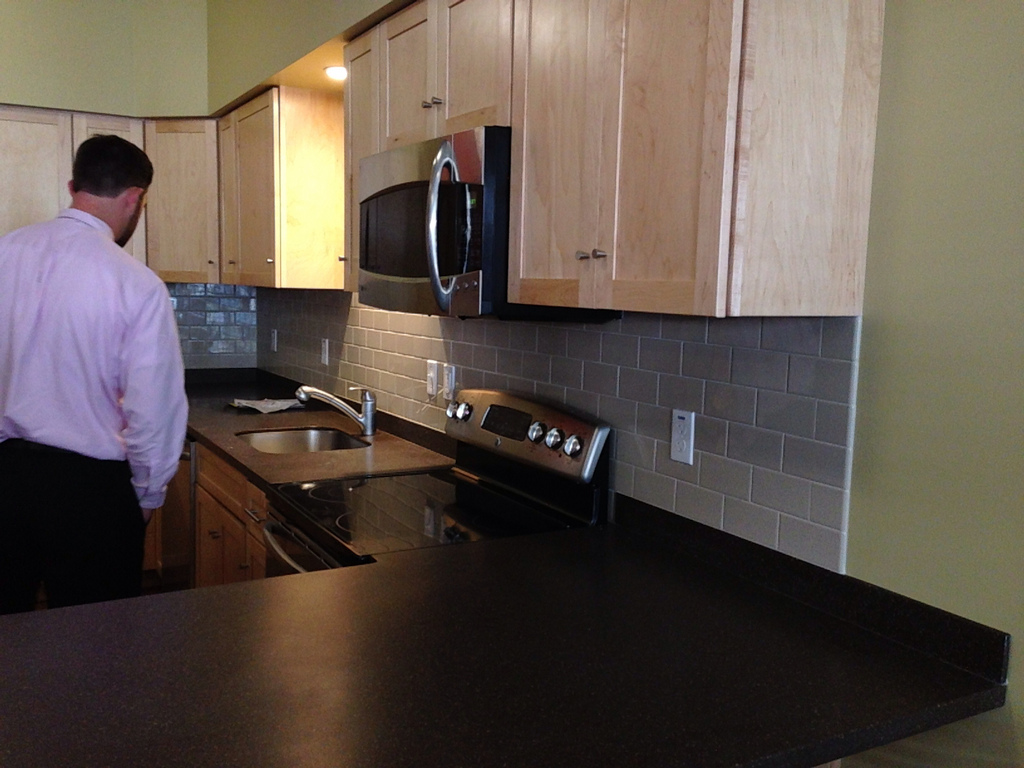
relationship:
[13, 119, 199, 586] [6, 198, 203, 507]
man in shirt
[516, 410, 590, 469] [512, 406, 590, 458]
knobs in row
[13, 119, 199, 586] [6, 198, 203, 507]
man wears shirt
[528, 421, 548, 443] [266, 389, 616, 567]
knobs on oven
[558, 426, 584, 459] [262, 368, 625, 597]
knob on stove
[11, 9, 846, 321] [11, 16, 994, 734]
cabinets in kitchen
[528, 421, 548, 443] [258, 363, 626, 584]
knobs on oven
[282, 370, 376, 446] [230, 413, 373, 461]
faucet on sink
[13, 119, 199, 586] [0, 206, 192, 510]
man wearing shirt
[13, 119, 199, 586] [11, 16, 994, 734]
man standing in kitchen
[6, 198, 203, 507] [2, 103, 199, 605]
shirt of man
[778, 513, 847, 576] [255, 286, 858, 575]
tile covering backsplash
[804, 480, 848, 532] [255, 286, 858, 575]
tile covering backsplash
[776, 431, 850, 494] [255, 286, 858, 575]
tile covering backsplash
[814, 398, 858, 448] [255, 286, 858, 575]
tile covering backsplash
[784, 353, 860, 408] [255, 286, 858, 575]
tile covering backsplash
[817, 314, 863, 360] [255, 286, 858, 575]
tile covering backsplash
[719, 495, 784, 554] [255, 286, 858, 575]
tile covering backsplash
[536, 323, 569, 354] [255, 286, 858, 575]
tile covering backsplash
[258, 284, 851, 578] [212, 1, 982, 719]
tile on wall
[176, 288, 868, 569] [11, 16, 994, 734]
backsplash in kitchen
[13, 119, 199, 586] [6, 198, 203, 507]
man has shirt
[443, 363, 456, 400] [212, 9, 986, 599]
switch on wall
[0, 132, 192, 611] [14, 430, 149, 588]
man has pants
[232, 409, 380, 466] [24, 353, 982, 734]
sink built into a countertop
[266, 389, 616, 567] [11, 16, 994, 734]
oven in a kitchen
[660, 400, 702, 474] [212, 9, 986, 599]
outlet in a wall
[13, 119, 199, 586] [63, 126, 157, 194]
man with hair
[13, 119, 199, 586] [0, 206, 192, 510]
man in shirt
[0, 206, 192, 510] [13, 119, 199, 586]
shirt on man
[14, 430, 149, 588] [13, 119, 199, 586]
pants on man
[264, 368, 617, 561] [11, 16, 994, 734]
oven in kitchen